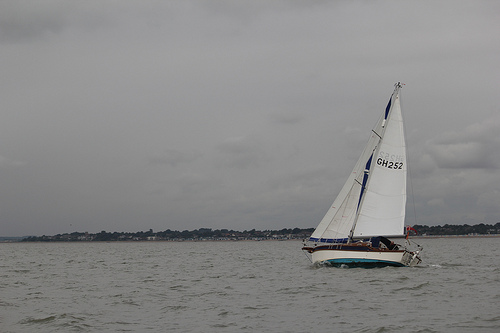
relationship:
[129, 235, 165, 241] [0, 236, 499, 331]
houses near water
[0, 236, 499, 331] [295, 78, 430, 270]
water under sail boat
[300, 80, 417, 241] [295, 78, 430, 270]
sail of sail boat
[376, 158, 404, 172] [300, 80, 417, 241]
writing across sail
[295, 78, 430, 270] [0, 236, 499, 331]
sail boat on top of water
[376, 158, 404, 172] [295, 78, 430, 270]
writing across sail boat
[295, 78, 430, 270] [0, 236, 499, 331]
sail boat floating on water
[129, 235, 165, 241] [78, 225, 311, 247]
houses on shore